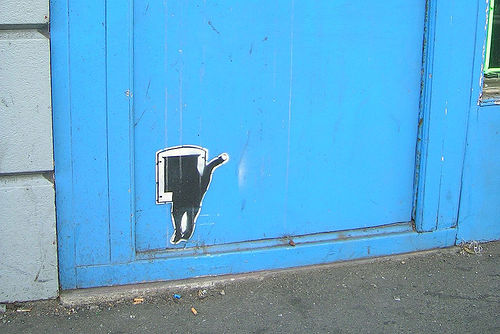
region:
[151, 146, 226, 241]
A painting of a cat in the door.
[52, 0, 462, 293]
A blue wooden door.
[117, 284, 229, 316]
Litter on the ground.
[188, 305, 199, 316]
A used cigarette butt on the ground.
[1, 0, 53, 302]
A blue cement wall.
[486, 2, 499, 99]
A green area of the building.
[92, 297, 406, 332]
The dark cement ground.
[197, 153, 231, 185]
The black cat's tail.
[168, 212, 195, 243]
The two back legs of the cat.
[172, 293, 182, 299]
A small blue piece of litter.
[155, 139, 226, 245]
graphic of cat going in pet door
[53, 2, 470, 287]
old door painted blue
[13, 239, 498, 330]
asphalt area outside of door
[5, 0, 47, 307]
large grey bricks of a wall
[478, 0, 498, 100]
corner of a window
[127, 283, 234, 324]
litter on ground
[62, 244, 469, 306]
concrete just visible under blue door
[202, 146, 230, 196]
tail of a painted black and white cat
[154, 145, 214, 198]
pet door painted on blue door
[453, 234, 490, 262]
trash on ground outside of door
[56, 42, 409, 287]
The door is blue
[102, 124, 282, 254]
This is a drawing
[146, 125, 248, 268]
The cat is black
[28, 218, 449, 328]
The street is black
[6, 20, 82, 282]
The bricks are light blue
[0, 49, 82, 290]
The bricks are large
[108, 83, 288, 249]
The cat door is white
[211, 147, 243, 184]
The end of the tail is white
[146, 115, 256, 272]
The cats backside is shown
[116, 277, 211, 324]
There are cigarette butts on the ground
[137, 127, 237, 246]
picture of a cat's rear end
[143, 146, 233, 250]
picture of cat entering pet door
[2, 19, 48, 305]
a concrete brick wall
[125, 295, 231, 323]
cigarette butts on sidewalk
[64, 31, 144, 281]
a bright blue door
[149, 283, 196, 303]
piece of used chewing gum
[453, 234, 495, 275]
garbage on the street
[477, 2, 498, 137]
a window without a frame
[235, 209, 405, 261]
dirt on a door frame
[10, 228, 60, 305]
scuff marks on a gray brick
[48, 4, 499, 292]
Blue door with a small opening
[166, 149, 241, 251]
A cat is entering though the opening of the door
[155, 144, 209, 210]
opening has white border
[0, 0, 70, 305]
Wall made of concrete blocks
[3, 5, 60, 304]
Wall is gray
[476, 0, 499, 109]
Window with green frame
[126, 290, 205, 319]
Cigarette maggots on the floor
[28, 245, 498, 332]
Sidewalk is concrete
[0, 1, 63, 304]
Wall is indented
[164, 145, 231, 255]
Cat is painted on paper